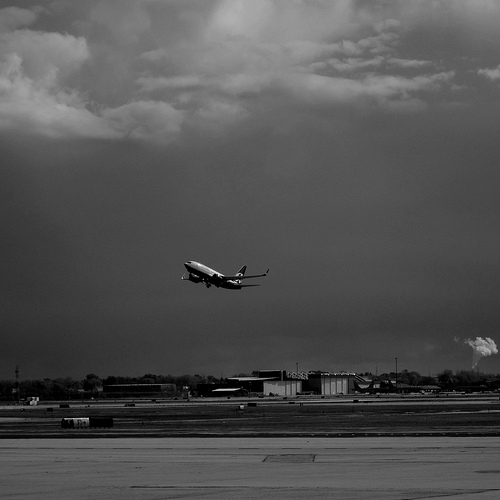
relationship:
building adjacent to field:
[307, 370, 356, 396] [130, 346, 415, 486]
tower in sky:
[4, 360, 29, 387] [155, 107, 327, 242]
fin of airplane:
[236, 256, 250, 279] [154, 229, 312, 333]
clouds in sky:
[0, 3, 499, 146] [0, 0, 500, 385]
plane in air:
[179, 259, 271, 292] [145, 167, 330, 254]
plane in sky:
[179, 244, 286, 309] [0, 0, 500, 385]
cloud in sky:
[0, 18, 93, 94] [0, 0, 500, 385]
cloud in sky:
[136, 3, 461, 118] [0, 0, 500, 385]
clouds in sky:
[472, 66, 500, 87] [0, 0, 500, 385]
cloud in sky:
[0, 1, 42, 30] [0, 0, 500, 385]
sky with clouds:
[0, 0, 500, 385] [161, 0, 441, 136]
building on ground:
[307, 370, 356, 396] [51, 362, 496, 489]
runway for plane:
[4, 420, 494, 484] [180, 257, 264, 291]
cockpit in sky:
[182, 257, 192, 264] [104, 128, 473, 235]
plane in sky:
[179, 259, 271, 292] [0, 0, 500, 385]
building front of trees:
[307, 370, 356, 396] [7, 369, 252, 394]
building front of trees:
[203, 382, 247, 398] [7, 369, 252, 394]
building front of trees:
[307, 370, 356, 396] [360, 367, 497, 392]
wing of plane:
[215, 268, 275, 280] [183, 258, 264, 293]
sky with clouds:
[206, 36, 435, 153] [18, 24, 478, 333]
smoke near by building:
[457, 333, 496, 362] [238, 331, 469, 446]